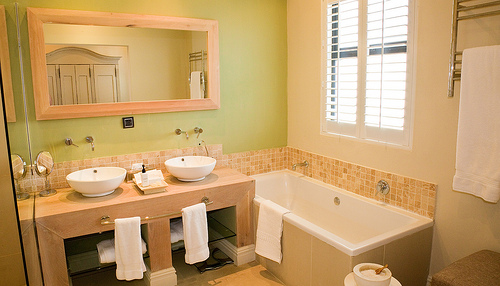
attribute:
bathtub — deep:
[248, 168, 434, 284]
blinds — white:
[301, 0, 443, 148]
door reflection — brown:
[45, 47, 120, 107]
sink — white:
[169, 151, 219, 188]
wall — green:
[220, 3, 318, 148]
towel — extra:
[453, 42, 496, 201]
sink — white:
[160, 153, 217, 183]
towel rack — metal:
[449, 2, 484, 85]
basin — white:
[66, 165, 127, 198]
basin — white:
[160, 153, 217, 182]